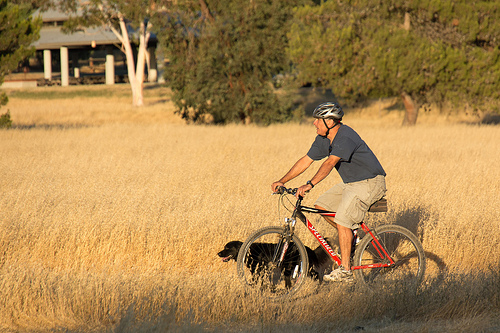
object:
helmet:
[311, 101, 344, 121]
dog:
[217, 235, 333, 297]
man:
[269, 100, 388, 284]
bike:
[234, 182, 427, 304]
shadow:
[330, 200, 449, 298]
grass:
[0, 39, 499, 331]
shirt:
[306, 124, 388, 186]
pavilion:
[33, 26, 167, 86]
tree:
[283, 0, 499, 127]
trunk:
[97, 3, 161, 109]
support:
[59, 45, 69, 87]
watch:
[306, 180, 315, 188]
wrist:
[305, 179, 317, 190]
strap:
[322, 116, 339, 139]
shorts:
[312, 172, 388, 230]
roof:
[26, 22, 205, 50]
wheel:
[351, 223, 428, 303]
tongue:
[219, 255, 231, 263]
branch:
[95, 0, 111, 25]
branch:
[401, 8, 415, 39]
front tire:
[236, 225, 311, 304]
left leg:
[321, 182, 375, 282]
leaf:
[398, 50, 413, 59]